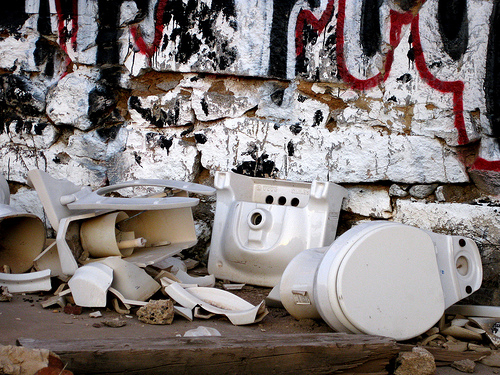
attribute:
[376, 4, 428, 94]
spray paint — Red 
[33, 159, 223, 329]
toilet — broken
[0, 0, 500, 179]
grafitti — white 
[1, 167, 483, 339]
toilet pieces — broken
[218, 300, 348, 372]
wood — rotted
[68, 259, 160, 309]
toilet pieces — broken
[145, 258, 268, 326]
toilet pieces — broken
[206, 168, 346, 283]
toilet pieces — broken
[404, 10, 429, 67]
coloring — red